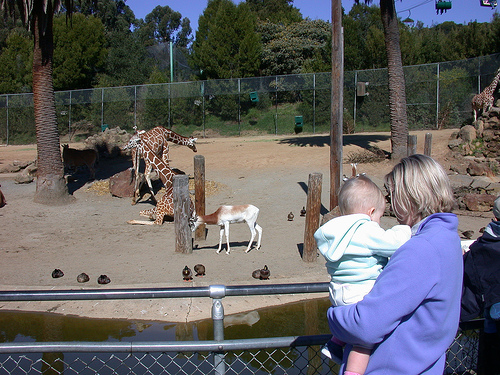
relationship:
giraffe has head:
[130, 115, 200, 205] [170, 125, 210, 157]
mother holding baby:
[379, 125, 469, 371] [311, 169, 412, 374]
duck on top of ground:
[91, 265, 126, 288] [6, 213, 357, 315]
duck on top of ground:
[74, 268, 93, 286] [6, 213, 357, 315]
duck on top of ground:
[40, 266, 72, 279] [6, 213, 357, 315]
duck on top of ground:
[248, 262, 279, 289] [6, 213, 357, 315]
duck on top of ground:
[180, 262, 197, 282] [6, 213, 357, 315]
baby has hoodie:
[311, 169, 412, 305] [315, 208, 406, 274]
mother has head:
[324, 152, 462, 374] [332, 177, 394, 241]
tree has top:
[205, 5, 271, 116] [209, 3, 253, 30]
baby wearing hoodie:
[311, 169, 412, 305] [315, 208, 406, 274]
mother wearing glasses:
[324, 152, 462, 374] [387, 182, 403, 219]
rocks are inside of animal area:
[453, 96, 499, 219] [4, 79, 497, 276]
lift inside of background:
[339, 4, 500, 35] [2, 4, 479, 89]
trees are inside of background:
[3, 12, 474, 102] [2, 4, 479, 89]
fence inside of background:
[0, 46, 496, 149] [2, 4, 479, 89]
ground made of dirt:
[6, 213, 357, 315] [36, 242, 131, 256]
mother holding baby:
[324, 152, 462, 374] [311, 169, 412, 305]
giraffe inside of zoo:
[123, 140, 198, 231] [5, 10, 471, 330]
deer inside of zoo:
[186, 206, 292, 257] [5, 10, 471, 330]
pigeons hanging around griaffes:
[276, 192, 332, 232] [113, 115, 221, 210]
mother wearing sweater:
[324, 152, 462, 374] [335, 208, 476, 372]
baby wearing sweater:
[311, 169, 412, 305] [335, 208, 476, 372]